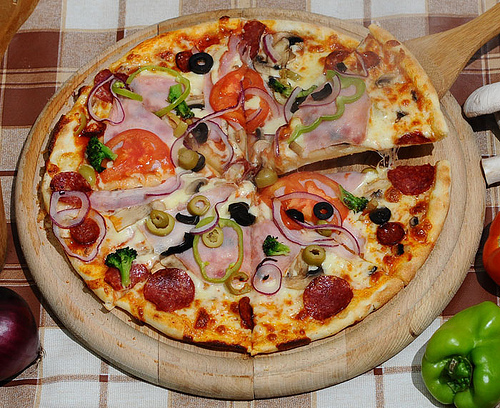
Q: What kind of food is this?
A: Pizza.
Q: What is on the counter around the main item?
A: Vegetables.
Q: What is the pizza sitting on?
A: Breadboard.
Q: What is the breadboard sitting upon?
A: Tablecloth.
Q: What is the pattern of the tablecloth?
A: Checkered.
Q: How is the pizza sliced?
A: Triangles.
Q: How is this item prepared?
A: In an oven.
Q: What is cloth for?
A: Table.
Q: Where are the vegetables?
A: On pizza.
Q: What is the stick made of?
A: Wood.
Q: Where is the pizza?
A: On tray.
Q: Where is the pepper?
A: On table.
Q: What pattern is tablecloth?
A: Checkered.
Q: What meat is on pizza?
A: Ham.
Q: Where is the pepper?
A: Next to pizza.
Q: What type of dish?
A: Serving.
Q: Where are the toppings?
A: On pizza.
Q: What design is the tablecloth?
A: Plaid.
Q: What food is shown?
A: Pizza.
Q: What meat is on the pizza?
A: Pepperoni.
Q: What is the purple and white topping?
A: Onion.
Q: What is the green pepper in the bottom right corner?
A: Bell pepper.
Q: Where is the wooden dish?
A: Under the pizza.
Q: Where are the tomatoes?
A: On the pizza.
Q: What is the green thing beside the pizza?
A: A pepper.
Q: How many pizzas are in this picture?
A: One.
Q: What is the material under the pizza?
A: Wood.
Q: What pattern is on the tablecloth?
A: Plaid.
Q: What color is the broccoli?
A: Green.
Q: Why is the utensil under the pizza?
A: To lift a slice.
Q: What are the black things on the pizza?
A: Olives.